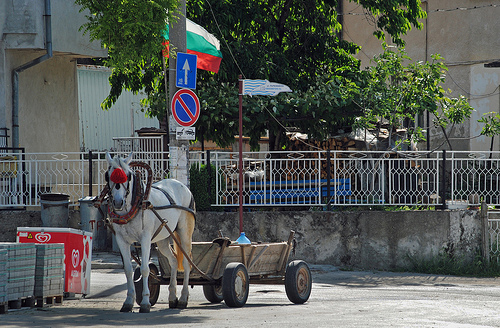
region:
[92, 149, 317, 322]
white horse pulling wagon on paved road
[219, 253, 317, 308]
two black wheels on side of wooden wagon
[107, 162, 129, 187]
red tassle hanging in front of horses head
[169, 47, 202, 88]
white arrow pointing up on blue sign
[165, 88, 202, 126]
blue circle with red line running through it on traffic sign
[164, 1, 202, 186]
two traffic signs attached to metal pole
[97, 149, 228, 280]
harness around horses neck and body attached to wooden wagon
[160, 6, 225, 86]
red, green and white flag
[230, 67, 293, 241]
white flag on red pole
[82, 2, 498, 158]
trees behind white fence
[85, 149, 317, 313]
horse pulling a wagon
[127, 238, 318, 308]
a wood wagon on wheels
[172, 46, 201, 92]
blue sign with white arrow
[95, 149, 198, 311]
a white horse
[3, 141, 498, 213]
a white metal fence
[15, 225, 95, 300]
a red and white container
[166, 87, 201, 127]
red and blue sign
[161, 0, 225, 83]
yellow, green and red flag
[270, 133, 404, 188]
stack of chopped wood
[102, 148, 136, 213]
red flower on the horses head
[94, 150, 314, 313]
Horse pulling a wagon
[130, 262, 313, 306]
Four black wagon wheels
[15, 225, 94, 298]
Red ice cream freezer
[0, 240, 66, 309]
Wood palates stacked with bricks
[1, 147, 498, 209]
Long white metal fence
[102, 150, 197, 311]
Large white horse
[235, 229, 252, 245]
Top of a plastic blue bottle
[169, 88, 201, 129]
Round red and blue sign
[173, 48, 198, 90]
White arrow on a square blue sign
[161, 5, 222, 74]
Red green and white flag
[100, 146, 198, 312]
Small white horse with red pom pom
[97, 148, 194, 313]
Small white horse hauling wooden wagon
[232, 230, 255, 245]
Blue bottle in wooden wagon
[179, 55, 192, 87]
White arrow on blue sign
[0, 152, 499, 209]
Long white metal fence on top of concrete wall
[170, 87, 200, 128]
Red and blue circular sign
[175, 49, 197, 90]
Blue arrow sign above circular sign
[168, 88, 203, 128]
Sign on pole behind small white horse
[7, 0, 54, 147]
Steel pole running up building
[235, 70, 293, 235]
Flagged street sign next to white metal fence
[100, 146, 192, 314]
a white horse on street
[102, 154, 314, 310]
still horse with trailer attached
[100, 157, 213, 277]
a harness on white horse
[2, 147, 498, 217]
a white metal fence on concrete wall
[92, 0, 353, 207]
a large green tree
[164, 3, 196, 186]
a pole with signs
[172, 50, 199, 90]
a blue sign with white up arrow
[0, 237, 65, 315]
two pallets of materials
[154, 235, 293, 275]
a small wooden trailer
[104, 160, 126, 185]
red decoration on horse face